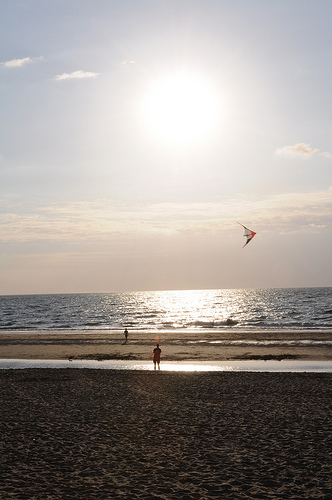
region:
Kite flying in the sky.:
[234, 219, 257, 249]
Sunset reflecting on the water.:
[131, 291, 253, 328]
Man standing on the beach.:
[150, 342, 163, 369]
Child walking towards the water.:
[121, 325, 130, 341]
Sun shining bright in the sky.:
[123, 63, 226, 160]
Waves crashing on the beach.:
[175, 316, 251, 330]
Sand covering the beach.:
[0, 368, 330, 498]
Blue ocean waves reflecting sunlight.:
[0, 288, 331, 328]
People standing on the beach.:
[121, 326, 163, 371]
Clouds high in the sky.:
[3, 48, 99, 85]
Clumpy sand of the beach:
[3, 362, 313, 499]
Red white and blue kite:
[237, 220, 263, 254]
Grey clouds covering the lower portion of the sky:
[1, 194, 327, 288]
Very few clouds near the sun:
[0, 0, 327, 197]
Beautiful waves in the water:
[0, 290, 326, 327]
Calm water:
[0, 344, 331, 376]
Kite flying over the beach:
[231, 222, 266, 255]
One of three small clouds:
[54, 63, 110, 88]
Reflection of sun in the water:
[110, 283, 244, 370]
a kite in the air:
[233, 218, 261, 250]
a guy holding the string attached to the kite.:
[151, 344, 163, 370]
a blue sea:
[2, 287, 330, 335]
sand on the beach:
[0, 374, 324, 498]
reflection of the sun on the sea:
[139, 286, 231, 324]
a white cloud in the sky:
[54, 69, 97, 87]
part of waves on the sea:
[184, 317, 291, 331]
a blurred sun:
[124, 61, 236, 146]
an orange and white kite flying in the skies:
[237, 221, 257, 248]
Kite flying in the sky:
[234, 221, 259, 251]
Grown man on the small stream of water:
[150, 338, 162, 371]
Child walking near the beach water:
[120, 324, 130, 342]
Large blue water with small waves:
[0, 285, 330, 327]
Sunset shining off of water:
[114, 289, 260, 326]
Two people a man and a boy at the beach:
[111, 327, 167, 369]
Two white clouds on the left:
[0, 42, 114, 86]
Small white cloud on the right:
[277, 137, 315, 162]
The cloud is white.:
[55, 63, 104, 93]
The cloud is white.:
[1, 50, 34, 71]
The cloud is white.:
[274, 139, 328, 165]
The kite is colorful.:
[210, 209, 274, 261]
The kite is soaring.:
[196, 199, 291, 267]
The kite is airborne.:
[181, 209, 274, 263]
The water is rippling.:
[0, 289, 331, 335]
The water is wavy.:
[1, 284, 331, 333]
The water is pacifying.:
[0, 282, 331, 340]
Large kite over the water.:
[238, 222, 257, 248]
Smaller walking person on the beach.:
[123, 327, 128, 342]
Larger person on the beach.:
[152, 343, 162, 370]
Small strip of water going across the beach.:
[1, 356, 331, 372]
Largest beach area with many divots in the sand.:
[0, 367, 331, 499]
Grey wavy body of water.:
[1, 287, 331, 332]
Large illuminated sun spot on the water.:
[130, 288, 251, 322]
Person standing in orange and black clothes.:
[152, 343, 161, 370]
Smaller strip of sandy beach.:
[1, 331, 331, 360]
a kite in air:
[238, 215, 271, 253]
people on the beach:
[111, 317, 171, 378]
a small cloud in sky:
[275, 139, 316, 166]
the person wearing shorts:
[147, 336, 174, 377]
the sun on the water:
[87, 277, 300, 323]